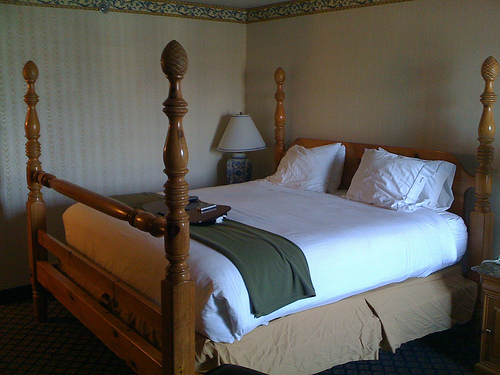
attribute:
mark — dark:
[103, 293, 120, 313]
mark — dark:
[63, 289, 75, 304]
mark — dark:
[168, 220, 179, 238]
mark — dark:
[58, 245, 78, 256]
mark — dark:
[127, 355, 137, 369]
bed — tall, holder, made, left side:
[21, 35, 499, 374]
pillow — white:
[345, 146, 431, 211]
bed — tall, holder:
[88, 137, 466, 287]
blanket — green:
[112, 185, 320, 322]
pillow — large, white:
[329, 138, 428, 234]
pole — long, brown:
[35, 166, 165, 240]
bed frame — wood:
[19, 52, 496, 373]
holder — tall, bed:
[207, 106, 274, 210]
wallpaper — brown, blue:
[104, 2, 346, 16]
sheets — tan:
[209, 298, 431, 346]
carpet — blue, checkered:
[348, 333, 486, 367]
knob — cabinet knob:
[481, 325, 498, 339]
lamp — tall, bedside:
[204, 104, 288, 178]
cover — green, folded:
[104, 192, 316, 317]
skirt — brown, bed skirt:
[218, 269, 472, 374]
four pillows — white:
[290, 148, 454, 210]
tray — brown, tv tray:
[134, 183, 234, 233]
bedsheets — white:
[60, 175, 465, 345]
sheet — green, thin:
[183, 229, 308, 314]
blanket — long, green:
[104, 189, 314, 319]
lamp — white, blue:
[202, 107, 272, 187]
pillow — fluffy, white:
[346, 144, 452, 211]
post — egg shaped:
[156, 38, 190, 81]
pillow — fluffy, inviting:
[361, 150, 426, 195]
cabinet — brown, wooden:
[42, 260, 178, 352]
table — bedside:
[473, 258, 499, 372]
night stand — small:
[468, 255, 498, 372]